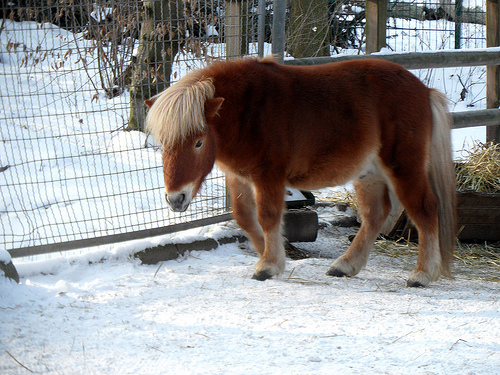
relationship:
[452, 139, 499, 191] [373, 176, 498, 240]
hay on box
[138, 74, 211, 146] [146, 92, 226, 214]
hair on head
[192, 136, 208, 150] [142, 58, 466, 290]
eye of a horse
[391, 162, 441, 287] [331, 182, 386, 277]
leg of a leg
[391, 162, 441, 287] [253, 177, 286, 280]
leg of a leg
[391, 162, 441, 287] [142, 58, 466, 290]
leg of a horse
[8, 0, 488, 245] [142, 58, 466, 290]
fence blocking horse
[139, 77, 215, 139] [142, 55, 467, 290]
mane of horse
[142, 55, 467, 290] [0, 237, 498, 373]
horse standing on snow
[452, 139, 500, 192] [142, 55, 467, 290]
hay behind horse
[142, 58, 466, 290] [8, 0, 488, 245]
horse inside a fence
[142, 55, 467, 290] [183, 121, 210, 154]
horse has eye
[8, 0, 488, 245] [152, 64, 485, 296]
fence behind pony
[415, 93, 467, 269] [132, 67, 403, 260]
tail on pony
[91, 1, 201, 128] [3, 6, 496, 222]
tree outside fence